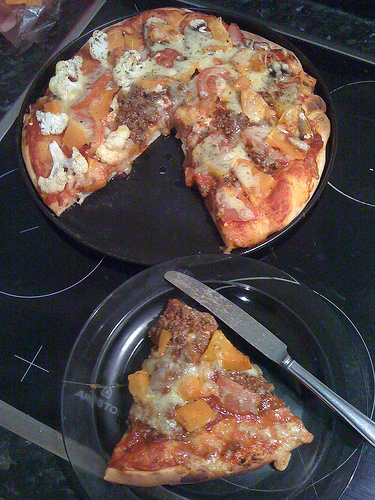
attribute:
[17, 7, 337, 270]
tray — stone, black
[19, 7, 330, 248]
pizza — missing, homemade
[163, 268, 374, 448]
knife — metal, dirty, silver, used, table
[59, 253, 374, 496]
plate — full, clear, circular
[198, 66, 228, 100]
tomato — red, sliced, orange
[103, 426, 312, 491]
crust — brown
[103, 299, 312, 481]
pizza — triangular, single, sliced, homemade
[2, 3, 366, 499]
table — black, granite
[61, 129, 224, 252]
section — gone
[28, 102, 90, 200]
sauce — red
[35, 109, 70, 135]
cauliflower — white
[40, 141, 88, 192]
cauliflower — white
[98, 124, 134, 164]
cauliflower — white, cooked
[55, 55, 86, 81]
cauliflower — white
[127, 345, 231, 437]
cheese — melted, white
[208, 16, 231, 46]
pepper — yellow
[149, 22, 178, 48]
pepper — yellow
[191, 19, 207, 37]
mushroom — cooked